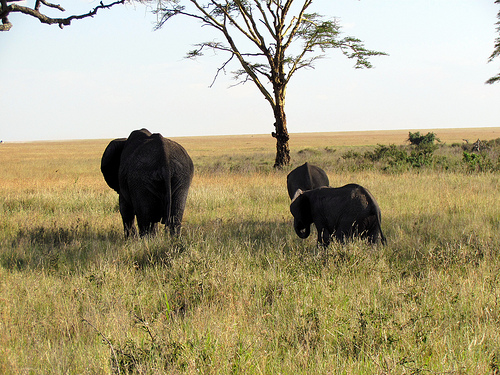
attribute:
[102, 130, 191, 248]
elephant — grey, walking, large, adult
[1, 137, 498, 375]
grass — tall, brown, green, high, dry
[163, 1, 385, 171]
tree — spindly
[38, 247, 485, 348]
grass — tall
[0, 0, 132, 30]
tree branch — High, gnarled , weathered  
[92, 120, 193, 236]
elephants — Adult 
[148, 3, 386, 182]
tree — Spindly 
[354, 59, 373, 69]
leaves — few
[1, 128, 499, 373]
plain — Open 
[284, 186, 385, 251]
elephant — grey, walking, small, herd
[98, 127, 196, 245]
elephant — Large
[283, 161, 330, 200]
elephant — grey, walking, Smaller 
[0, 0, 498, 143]
sky — white, blue, pale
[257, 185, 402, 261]
elephant — baby 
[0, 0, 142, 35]
tree branch — tree's, without leaves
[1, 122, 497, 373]
ground — higher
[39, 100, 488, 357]
grass — green, white, beige, dehydrated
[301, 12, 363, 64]
leaves — green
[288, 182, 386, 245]
elephant — small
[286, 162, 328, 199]
elephant —  small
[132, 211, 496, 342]
grass — dehydrated , Tall, pale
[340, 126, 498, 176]
vegetation — darker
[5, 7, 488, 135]
sky. — blue 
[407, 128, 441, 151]
vegetation — darker, green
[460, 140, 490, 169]
vegetation — darker, green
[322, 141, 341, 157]
vegetation — darker, green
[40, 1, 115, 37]
branch — gnarled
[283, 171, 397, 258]
elephant — Baby 